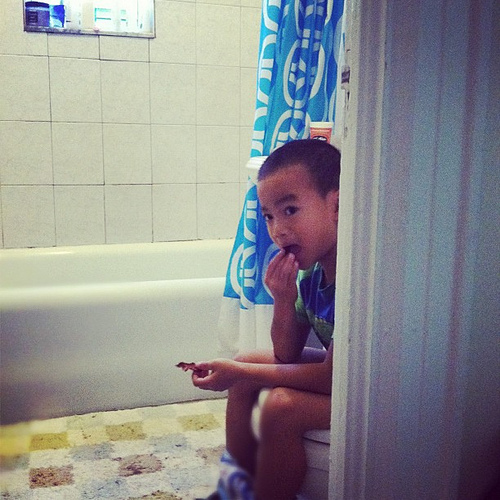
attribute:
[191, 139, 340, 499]
boy — eating, young, leaning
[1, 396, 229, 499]
rug — bright, checkered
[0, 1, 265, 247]
wall — white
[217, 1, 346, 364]
curtain — blue, white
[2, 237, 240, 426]
tub — white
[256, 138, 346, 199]
hair — short, black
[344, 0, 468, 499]
frame — white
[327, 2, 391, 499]
door — white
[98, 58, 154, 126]
tile — white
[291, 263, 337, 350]
shirt — blue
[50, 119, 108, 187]
tile — white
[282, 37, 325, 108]
circle — white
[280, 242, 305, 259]
mouth — open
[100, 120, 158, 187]
tile — white